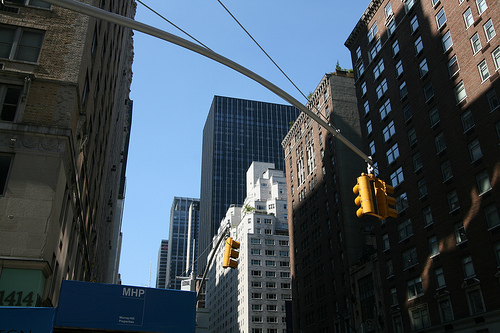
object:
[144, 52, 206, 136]
this is the sky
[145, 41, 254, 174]
sky is clear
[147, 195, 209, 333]
two buildings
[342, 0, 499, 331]
building has windows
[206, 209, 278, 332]
building is white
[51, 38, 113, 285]
made of stone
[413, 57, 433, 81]
windows are closed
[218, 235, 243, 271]
stoplight is yellow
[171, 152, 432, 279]
three stoplights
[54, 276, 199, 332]
box is blue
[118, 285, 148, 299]
"mhp"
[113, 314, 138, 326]
written on box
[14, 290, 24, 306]
number on building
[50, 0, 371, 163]
pole is silver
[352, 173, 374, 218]
part of trafficlight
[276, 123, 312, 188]
edge of building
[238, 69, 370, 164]
part of metal post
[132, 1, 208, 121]
part of blue sky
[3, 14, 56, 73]
window on building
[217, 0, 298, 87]
part of a string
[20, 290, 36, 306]
part of a number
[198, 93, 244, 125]
top of a building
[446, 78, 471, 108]
windows on a buildin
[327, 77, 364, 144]
part of building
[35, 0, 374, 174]
metal pole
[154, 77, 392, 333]
row of buildings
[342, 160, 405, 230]
light hanging on pol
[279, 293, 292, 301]
windows on building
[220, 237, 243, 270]
lights on traffic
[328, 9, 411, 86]
corner of building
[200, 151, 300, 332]
tall gray building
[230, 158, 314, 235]
top of building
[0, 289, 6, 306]
numbers on building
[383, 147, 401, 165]
reflection on window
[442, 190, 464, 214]
blind partially open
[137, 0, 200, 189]
blue daytime sky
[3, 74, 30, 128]
with no curtain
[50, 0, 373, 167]
pole for light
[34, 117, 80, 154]
ornamental design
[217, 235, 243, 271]
view of street light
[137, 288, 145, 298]
3 white letters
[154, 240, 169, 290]
building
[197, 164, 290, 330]
casing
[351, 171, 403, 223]
stoplight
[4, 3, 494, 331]
picture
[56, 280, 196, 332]
box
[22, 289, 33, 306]
number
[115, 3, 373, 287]
sky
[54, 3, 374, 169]
pole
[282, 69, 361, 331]
building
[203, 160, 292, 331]
building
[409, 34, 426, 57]
windows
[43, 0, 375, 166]
post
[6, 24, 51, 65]
window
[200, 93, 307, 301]
buildings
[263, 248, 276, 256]
windows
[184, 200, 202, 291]
building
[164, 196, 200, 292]
building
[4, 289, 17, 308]
numbers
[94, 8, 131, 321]
building